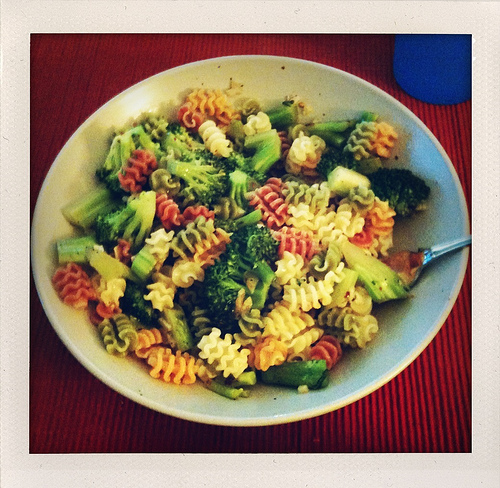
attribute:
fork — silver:
[384, 231, 467, 278]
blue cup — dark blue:
[392, 33, 472, 111]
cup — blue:
[396, 39, 473, 111]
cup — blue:
[390, 33, 472, 105]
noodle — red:
[49, 100, 418, 386]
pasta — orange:
[50, 261, 99, 310]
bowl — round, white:
[28, 54, 468, 429]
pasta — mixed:
[151, 342, 196, 383]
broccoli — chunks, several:
[306, 115, 370, 146]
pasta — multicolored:
[276, 255, 321, 302]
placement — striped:
[381, 383, 464, 443]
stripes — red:
[402, 375, 456, 440]